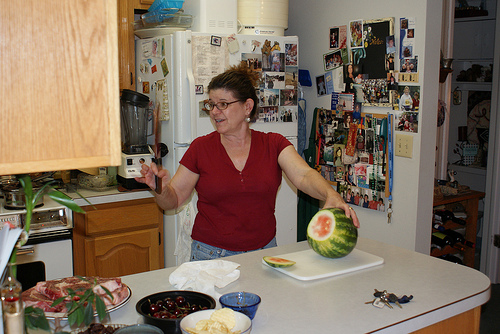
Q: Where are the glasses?
A: On face.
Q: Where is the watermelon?
A: On cutting board.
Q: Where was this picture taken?
A: Kitchen.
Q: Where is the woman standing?
A: Kitchen.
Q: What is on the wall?
A: Pictures.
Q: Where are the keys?
A: On counter.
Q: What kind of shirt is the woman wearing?
A: Short Sleeve.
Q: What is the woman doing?
A: Preparing food.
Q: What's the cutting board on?
A: Counter.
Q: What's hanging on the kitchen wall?
A: Pictures.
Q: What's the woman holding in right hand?
A: Large knife.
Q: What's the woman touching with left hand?
A: Watermelon.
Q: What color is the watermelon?
A: Green, red and white.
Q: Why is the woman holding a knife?
A: She is using it to cut the watermelon.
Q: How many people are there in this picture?
A: One.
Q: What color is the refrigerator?
A: White.